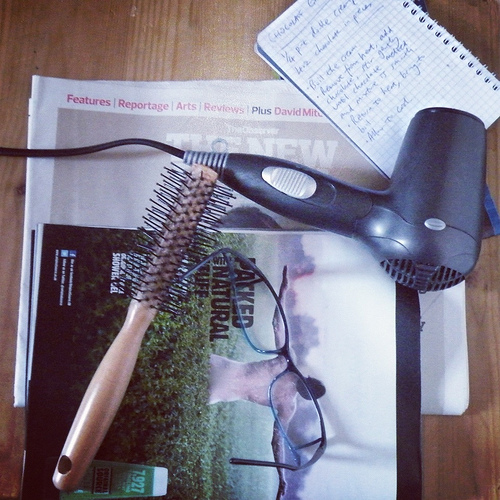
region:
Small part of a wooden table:
[156, 15, 209, 63]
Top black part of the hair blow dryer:
[409, 120, 481, 260]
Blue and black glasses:
[227, 277, 317, 483]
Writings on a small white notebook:
[301, 17, 402, 108]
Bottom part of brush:
[47, 359, 126, 483]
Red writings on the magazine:
[59, 86, 229, 114]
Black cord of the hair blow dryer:
[1, 132, 156, 180]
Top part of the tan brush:
[138, 175, 213, 310]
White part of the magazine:
[426, 354, 461, 386]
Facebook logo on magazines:
[69, 245, 77, 260]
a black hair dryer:
[181, 105, 490, 294]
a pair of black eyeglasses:
[172, 242, 327, 471]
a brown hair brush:
[48, 157, 235, 489]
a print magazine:
[24, 222, 396, 498]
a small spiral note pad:
[257, 0, 498, 176]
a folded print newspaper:
[14, 74, 471, 416]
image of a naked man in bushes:
[212, 261, 327, 497]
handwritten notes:
[267, 0, 429, 146]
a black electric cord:
[1, 136, 187, 158]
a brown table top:
[1, 0, 498, 495]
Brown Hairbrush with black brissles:
[50, 154, 223, 480]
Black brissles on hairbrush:
[146, 148, 192, 300]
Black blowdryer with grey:
[167, 92, 473, 272]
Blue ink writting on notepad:
[310, 73, 405, 115]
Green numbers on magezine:
[107, 466, 171, 498]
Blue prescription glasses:
[247, 254, 315, 470]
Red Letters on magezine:
[64, 89, 246, 115]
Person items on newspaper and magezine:
[54, 103, 466, 455]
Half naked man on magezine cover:
[145, 269, 330, 436]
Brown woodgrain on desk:
[448, 391, 493, 483]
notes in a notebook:
[256, 12, 462, 152]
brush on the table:
[54, 127, 244, 498]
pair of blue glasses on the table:
[176, 232, 365, 497]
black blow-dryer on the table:
[131, 44, 488, 334]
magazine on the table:
[16, 212, 411, 495]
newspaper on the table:
[6, 38, 498, 430]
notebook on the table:
[145, 5, 488, 422]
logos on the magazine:
[44, 240, 89, 324]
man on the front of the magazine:
[199, 237, 374, 497]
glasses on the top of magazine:
[123, 200, 382, 497]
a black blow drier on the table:
[183, 105, 484, 292]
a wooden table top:
[0, 0, 497, 497]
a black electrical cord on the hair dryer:
[0, 135, 185, 160]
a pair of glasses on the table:
[173, 245, 328, 470]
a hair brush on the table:
[50, 158, 237, 488]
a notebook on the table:
[253, 0, 498, 177]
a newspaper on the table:
[12, 74, 469, 414]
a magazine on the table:
[25, 220, 422, 499]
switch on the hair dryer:
[261, 163, 333, 209]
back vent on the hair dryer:
[379, 255, 465, 294]